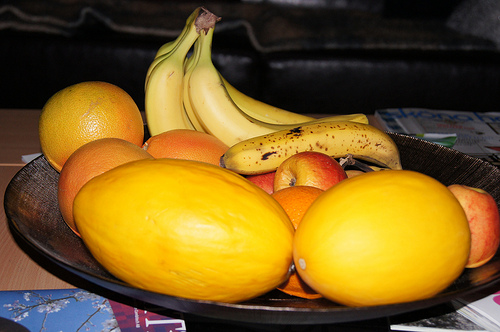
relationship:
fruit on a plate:
[36, 5, 500, 308] [5, 102, 499, 330]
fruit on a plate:
[288, 162, 470, 312] [5, 102, 499, 330]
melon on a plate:
[279, 159, 473, 321] [1, 124, 481, 330]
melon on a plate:
[66, 162, 297, 293] [1, 124, 481, 330]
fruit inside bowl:
[36, 5, 500, 308] [4, 125, 499, 326]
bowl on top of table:
[4, 125, 499, 326] [1, 98, 499, 327]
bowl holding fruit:
[4, 125, 499, 326] [36, 5, 500, 308]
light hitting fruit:
[145, 198, 269, 258] [36, 13, 491, 330]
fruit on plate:
[36, 5, 500, 308] [1, 124, 481, 330]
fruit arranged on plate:
[36, 5, 500, 308] [5, 102, 499, 330]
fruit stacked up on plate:
[36, 5, 500, 308] [1, 124, 481, 330]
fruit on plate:
[36, 5, 500, 308] [23, 94, 495, 314]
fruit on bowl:
[63, 73, 456, 325] [37, 39, 487, 324]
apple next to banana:
[244, 142, 359, 223] [219, 121, 404, 175]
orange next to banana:
[34, 75, 141, 162] [140, 18, 198, 128]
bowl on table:
[4, 129, 500, 326] [1, 108, 37, 157]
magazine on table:
[369, 102, 499, 162] [1, 98, 499, 327]